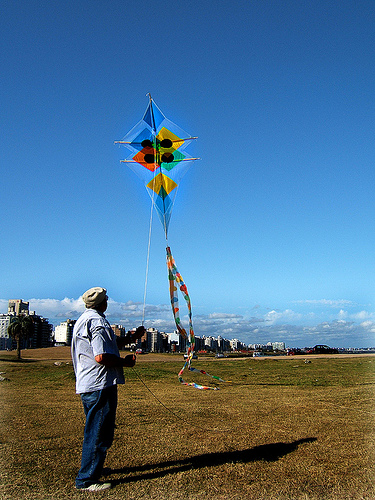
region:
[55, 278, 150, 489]
man standing on grass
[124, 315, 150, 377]
two hands holding string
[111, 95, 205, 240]
multi colored kite in sky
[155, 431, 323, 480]
shadow of man on grass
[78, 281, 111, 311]
gray cap on man's head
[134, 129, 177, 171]
colored design on kite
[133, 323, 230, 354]
line of city buildings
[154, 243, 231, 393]
tail on bottom of kite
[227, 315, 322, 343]
gray clouds low in sky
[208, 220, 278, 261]
clear blue daytime sky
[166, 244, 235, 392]
Tail of multi-colored tail.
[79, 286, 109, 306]
Gray man's hat.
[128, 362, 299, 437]
String attached to kite.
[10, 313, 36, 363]
Lone palm tree in field.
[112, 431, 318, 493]
Man's shadow cast on ground.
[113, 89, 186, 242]
Main section of kite in mid-air.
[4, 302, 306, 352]
Building line the landscape.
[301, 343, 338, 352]
Black pickup truck parked.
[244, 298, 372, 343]
Blue sky with cloudys.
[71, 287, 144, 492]
Man flying kite.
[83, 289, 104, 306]
The hat the man is wearing.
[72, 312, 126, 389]
The blue shirt the man is wearing.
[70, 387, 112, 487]
The blue jeans the man is wearing.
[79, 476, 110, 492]
The white sneakers the man is wearing.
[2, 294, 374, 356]
The buildings in the background.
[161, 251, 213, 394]
The colorful dots on the tail of the kite.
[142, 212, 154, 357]
The string of the kite in the man's hand.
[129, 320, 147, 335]
The left hand of the man flying the kite.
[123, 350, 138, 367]
The right hand of the man flying the kite.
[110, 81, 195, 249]
The kite flying in the air.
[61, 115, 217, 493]
man flying a kite in the wind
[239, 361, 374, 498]
large open grass field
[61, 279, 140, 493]
man wearing blue jeans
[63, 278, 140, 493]
man wearing short sleeve blue shirt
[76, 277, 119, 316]
light colored hat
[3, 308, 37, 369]
tall green tree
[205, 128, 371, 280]
section of blue sky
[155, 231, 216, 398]
colorful kite tail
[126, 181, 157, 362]
kite string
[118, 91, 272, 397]
long multicolored kite in the air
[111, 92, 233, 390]
blue, yellow and orange kite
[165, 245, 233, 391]
polka dot tail on a kite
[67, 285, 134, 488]
elderly man in white hat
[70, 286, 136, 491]
man in blue jeans standing in an open field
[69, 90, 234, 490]
elderly man flying a kite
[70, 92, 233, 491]
man flying a yellow, blue and orange kite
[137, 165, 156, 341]
white twine attached to the kite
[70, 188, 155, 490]
man holding a twine to an orange, blue and yellow kite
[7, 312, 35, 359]
palm tree on the field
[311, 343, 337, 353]
small black car parked next to the park